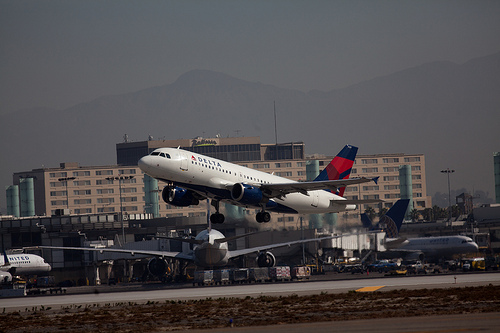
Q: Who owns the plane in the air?
A: Delta.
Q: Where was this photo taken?
A: Airport.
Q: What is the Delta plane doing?
A: Taking off.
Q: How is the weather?
A: Hazy.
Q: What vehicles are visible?
A: Planes.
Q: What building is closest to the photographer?
A: Airport.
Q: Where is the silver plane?
A: Next to the United plane.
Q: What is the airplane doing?
A: Taking off.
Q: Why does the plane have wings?
A: To be able to fly.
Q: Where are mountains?
A: In the far distance.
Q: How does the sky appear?
A: Overcast.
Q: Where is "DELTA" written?
A: On side of plane.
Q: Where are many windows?
A: On a building.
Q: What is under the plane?
A: Black wheels.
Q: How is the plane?
A: Rising.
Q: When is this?
A: Daytime.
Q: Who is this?
A: No one.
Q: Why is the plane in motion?
A: Travelling.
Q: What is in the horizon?
A: Hills.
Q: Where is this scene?
A: At the airport.